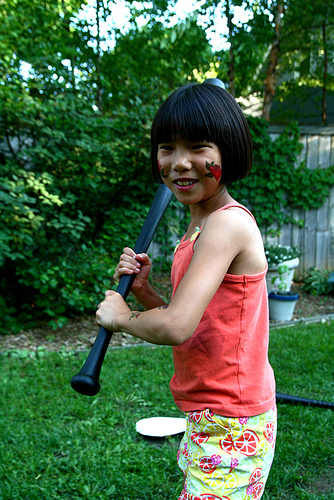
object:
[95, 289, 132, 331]
hand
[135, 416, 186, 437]
racket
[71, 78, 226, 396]
bat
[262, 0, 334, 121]
tree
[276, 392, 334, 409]
baseball bat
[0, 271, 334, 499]
ground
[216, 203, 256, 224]
strap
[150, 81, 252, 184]
hair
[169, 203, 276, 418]
top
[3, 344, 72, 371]
leaves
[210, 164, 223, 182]
flower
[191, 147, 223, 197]
cheek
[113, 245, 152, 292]
hand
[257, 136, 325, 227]
plants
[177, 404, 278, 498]
shorts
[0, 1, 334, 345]
leaves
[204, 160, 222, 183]
flower tattoo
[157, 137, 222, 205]
face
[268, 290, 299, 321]
pots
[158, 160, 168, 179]
flower tattoo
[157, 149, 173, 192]
cheek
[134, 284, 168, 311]
arm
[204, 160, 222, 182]
drawing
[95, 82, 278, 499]
girl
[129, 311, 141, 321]
drawing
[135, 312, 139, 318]
rose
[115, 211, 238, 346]
arm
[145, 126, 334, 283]
fence